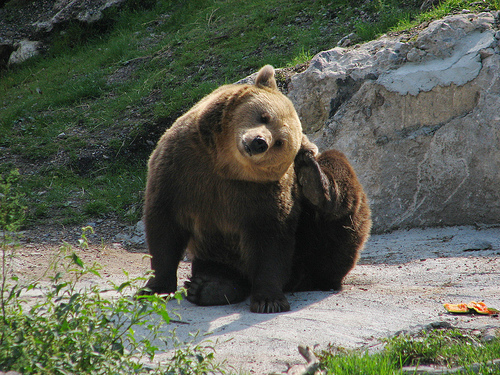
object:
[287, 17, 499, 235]
rock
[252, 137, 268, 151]
nose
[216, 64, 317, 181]
head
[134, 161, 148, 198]
weeds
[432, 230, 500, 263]
ground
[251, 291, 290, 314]
bear paw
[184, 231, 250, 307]
leg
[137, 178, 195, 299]
leg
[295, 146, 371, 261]
bear leg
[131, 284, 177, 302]
bear paw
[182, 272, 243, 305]
bear paw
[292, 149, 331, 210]
bear paw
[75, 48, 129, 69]
grass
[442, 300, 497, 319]
object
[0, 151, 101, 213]
green grass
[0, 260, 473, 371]
ground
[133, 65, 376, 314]
bear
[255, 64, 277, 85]
ear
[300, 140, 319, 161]
ear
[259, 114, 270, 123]
eye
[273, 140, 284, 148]
eye